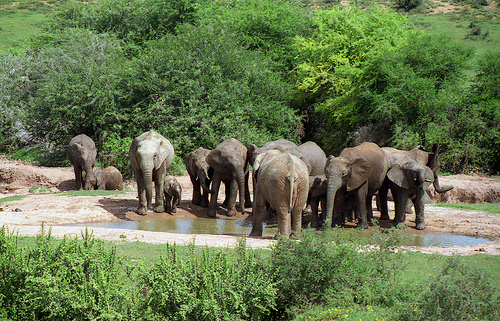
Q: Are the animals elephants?
A: Yes, all the animals are elephants.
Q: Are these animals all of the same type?
A: Yes, all the animals are elephants.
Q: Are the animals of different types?
A: No, all the animals are elephants.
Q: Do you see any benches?
A: No, there are no benches.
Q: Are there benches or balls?
A: No, there are no benches or balls.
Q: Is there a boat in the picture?
A: No, there are no boats.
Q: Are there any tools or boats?
A: No, there are no boats or tools.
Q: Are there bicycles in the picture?
A: No, there are no bicycles.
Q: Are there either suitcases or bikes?
A: No, there are no bikes or suitcases.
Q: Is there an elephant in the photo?
A: Yes, there is an elephant.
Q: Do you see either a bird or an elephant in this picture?
A: Yes, there is an elephant.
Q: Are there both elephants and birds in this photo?
A: No, there is an elephant but no birds.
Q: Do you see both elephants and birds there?
A: No, there is an elephant but no birds.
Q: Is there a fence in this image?
A: No, there are no fences.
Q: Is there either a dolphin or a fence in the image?
A: No, there are no fences or dolphins.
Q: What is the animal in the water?
A: The animal is an elephant.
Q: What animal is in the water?
A: The animal is an elephant.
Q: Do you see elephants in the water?
A: Yes, there is an elephant in the water.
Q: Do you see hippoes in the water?
A: No, there is an elephant in the water.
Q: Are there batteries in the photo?
A: No, there are no batteries.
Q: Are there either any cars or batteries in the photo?
A: No, there are no batteries or cars.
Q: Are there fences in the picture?
A: No, there are no fences.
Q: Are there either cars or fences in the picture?
A: No, there are no fences or cars.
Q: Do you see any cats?
A: No, there are no cats.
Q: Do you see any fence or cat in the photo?
A: No, there are no cats or fences.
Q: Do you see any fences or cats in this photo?
A: No, there are no cats or fences.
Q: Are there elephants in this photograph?
A: Yes, there is an elephant.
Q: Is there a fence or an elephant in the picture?
A: Yes, there is an elephant.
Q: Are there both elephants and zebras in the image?
A: No, there is an elephant but no zebras.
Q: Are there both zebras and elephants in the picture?
A: No, there is an elephant but no zebras.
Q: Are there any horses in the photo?
A: No, there are no horses.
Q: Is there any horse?
A: No, there are no horses.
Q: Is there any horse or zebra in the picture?
A: No, there are no horses or zebras.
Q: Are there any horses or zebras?
A: No, there are no horses or zebras.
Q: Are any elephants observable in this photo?
A: Yes, there is an elephant.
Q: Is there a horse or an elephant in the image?
A: Yes, there is an elephant.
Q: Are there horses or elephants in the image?
A: Yes, there is an elephant.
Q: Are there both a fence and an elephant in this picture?
A: No, there is an elephant but no fences.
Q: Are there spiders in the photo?
A: No, there are no spiders.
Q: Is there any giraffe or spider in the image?
A: No, there are no spiders or giraffes.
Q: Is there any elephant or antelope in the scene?
A: Yes, there is an elephant.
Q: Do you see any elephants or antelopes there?
A: Yes, there is an elephant.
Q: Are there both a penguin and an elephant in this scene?
A: No, there is an elephant but no penguins.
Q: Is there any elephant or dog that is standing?
A: Yes, the elephant is standing.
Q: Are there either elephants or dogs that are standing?
A: Yes, the elephant is standing.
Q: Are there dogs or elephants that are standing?
A: Yes, the elephant is standing.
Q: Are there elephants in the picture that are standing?
A: Yes, there is an elephant that is standing.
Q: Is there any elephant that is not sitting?
A: Yes, there is an elephant that is standing.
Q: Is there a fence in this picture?
A: No, there are no fences.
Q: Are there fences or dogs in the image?
A: No, there are no fences or dogs.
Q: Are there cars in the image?
A: No, there are no cars.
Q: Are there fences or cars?
A: No, there are no cars or fences.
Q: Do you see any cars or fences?
A: No, there are no cars or fences.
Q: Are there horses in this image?
A: No, there are no horses.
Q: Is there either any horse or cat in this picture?
A: No, there are no horses or cats.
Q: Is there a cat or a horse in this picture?
A: No, there are no horses or cats.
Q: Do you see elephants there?
A: Yes, there is an elephant.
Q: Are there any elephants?
A: Yes, there is an elephant.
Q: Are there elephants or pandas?
A: Yes, there is an elephant.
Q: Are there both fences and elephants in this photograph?
A: No, there is an elephant but no fences.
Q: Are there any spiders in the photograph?
A: No, there are no spiders.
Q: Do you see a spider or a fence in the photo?
A: No, there are no spiders or fences.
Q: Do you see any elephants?
A: Yes, there is an elephant.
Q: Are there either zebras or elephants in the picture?
A: Yes, there is an elephant.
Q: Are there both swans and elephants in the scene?
A: No, there is an elephant but no swans.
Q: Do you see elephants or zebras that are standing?
A: Yes, the elephant is standing.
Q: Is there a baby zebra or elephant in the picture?
A: Yes, there is a baby elephant.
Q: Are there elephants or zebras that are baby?
A: Yes, the elephant is a baby.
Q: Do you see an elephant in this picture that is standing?
A: Yes, there is an elephant that is standing.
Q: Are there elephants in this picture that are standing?
A: Yes, there is an elephant that is standing.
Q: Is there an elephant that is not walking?
A: Yes, there is an elephant that is standing.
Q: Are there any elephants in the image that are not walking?
A: Yes, there is an elephant that is standing.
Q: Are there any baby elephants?
A: Yes, there is a baby elephant.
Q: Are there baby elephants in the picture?
A: Yes, there is a baby elephant.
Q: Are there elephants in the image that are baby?
A: Yes, there is a baby elephant.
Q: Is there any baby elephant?
A: Yes, there is a baby elephant.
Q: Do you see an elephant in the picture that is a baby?
A: Yes, there is an elephant that is a baby.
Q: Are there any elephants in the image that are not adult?
A: Yes, there is an baby elephant.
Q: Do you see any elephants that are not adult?
A: Yes, there is an baby elephant.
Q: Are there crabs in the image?
A: No, there are no crabs.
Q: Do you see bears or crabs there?
A: No, there are no crabs or bears.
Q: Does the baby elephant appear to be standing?
A: Yes, the elephant is standing.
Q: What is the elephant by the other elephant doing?
A: The elephant is standing.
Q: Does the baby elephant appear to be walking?
A: No, the elephant is standing.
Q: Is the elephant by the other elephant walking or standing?
A: The elephant is standing.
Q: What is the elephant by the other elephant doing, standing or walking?
A: The elephant is standing.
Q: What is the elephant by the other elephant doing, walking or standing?
A: The elephant is standing.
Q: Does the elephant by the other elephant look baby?
A: Yes, the elephant is a baby.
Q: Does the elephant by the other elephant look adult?
A: No, the elephant is a baby.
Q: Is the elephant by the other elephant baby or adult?
A: The elephant is a baby.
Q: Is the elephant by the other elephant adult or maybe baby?
A: The elephant is a baby.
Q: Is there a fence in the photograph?
A: No, there are no fences.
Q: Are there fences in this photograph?
A: No, there are no fences.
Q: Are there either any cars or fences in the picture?
A: No, there are no fences or cars.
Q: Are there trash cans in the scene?
A: No, there are no trash cans.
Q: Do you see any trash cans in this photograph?
A: No, there are no trash cans.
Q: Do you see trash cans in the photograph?
A: No, there are no trash cans.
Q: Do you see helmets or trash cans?
A: No, there are no trash cans or helmets.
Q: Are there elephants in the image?
A: Yes, there is an elephant.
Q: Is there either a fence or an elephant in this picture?
A: Yes, there is an elephant.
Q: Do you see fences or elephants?
A: Yes, there is an elephant.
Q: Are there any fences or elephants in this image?
A: Yes, there is an elephant.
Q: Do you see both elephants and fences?
A: No, there is an elephant but no fences.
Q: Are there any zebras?
A: No, there are no zebras.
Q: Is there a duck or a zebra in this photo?
A: No, there are no zebras or ducks.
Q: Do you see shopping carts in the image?
A: No, there are no shopping carts.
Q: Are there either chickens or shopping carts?
A: No, there are no shopping carts or chickens.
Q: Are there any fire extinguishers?
A: No, there are no fire extinguishers.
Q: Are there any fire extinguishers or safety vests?
A: No, there are no fire extinguishers or safety vests.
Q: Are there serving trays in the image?
A: No, there are no serving trays.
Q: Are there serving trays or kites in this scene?
A: No, there are no serving trays or kites.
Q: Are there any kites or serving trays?
A: No, there are no serving trays or kites.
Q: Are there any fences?
A: No, there are no fences.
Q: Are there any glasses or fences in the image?
A: No, there are no fences or glasses.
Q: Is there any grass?
A: Yes, there is grass.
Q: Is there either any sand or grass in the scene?
A: Yes, there is grass.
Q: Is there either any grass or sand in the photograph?
A: Yes, there is grass.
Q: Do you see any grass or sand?
A: Yes, there is grass.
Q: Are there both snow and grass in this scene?
A: No, there is grass but no snow.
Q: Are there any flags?
A: No, there are no flags.